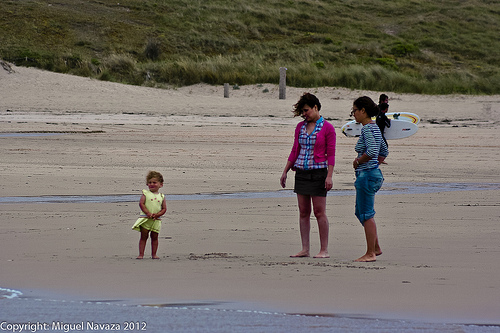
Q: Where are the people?
A: Beach.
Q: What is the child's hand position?
A: Clasped.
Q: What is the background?
A: Greenery.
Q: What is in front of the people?
A: Water.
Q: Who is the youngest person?
A: Little girl.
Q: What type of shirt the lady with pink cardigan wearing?
A: Plaid shirt.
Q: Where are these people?
A: At the beach.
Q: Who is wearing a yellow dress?
A: The little girl.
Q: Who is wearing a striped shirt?
A: The woman on the right.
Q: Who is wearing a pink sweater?
A: The woman in the middle.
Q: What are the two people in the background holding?
A: Surfboards.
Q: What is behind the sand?
A: Grassy dunes.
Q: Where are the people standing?
A: In the sand.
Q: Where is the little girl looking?
A: To her right.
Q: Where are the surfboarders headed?
A: To the water.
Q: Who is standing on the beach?
A: A child, two women and two surfers.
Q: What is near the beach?
A: Trees.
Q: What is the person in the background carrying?
A: A surfboard.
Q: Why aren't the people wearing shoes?
A: They're on the beach.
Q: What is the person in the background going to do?
A: Surf.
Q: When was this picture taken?
A: During the day.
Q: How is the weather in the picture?
A: Windy.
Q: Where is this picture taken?
A: At the beach.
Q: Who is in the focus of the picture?
A: Two women and a baby.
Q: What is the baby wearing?
A: A romper.